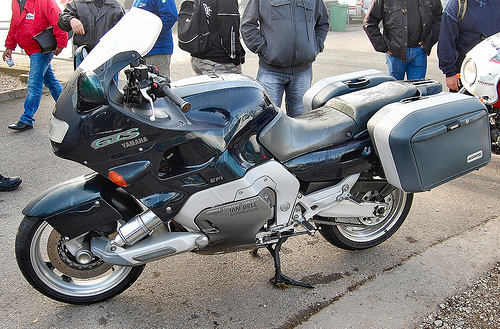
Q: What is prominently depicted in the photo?
A: A motorcycle.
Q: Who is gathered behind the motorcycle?
A: A crowd of people.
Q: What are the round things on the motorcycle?
A: The wheels.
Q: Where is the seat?
A: On the motorcycle.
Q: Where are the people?
A: By the motorcycle.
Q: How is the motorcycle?
A: Parked.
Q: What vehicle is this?
A: Motorcycle.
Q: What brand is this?
A: Yamaha.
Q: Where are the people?
A: Behind the motorcycle.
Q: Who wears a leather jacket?
A: The man.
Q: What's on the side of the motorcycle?
A: A bag.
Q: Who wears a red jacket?
A: The man in the left hand corner..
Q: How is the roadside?
A: Rough.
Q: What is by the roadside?
A: A motorcycle.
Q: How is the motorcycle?
A: Grey.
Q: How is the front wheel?
A: Small and round.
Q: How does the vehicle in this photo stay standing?
A: Kickstand.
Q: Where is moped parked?
A: On street.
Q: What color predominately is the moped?
A: Blue.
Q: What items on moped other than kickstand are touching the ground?
A: Tires.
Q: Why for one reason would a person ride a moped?
A: Transportation.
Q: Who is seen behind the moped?
A: People.